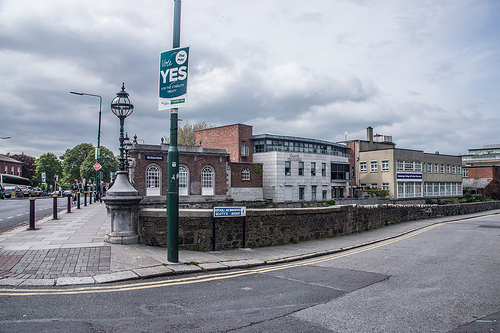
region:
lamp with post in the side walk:
[63, 87, 103, 202]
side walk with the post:
[40, 238, 292, 263]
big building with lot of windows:
[353, 140, 470, 197]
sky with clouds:
[268, 60, 456, 118]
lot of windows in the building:
[396, 161, 459, 190]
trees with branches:
[46, 145, 106, 176]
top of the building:
[259, 129, 336, 150]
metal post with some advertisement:
[153, 53, 195, 267]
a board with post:
[208, 206, 252, 254]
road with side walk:
[7, 187, 109, 279]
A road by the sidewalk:
[1, 210, 498, 330]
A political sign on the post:
[158, 50, 187, 107]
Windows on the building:
[147, 163, 217, 191]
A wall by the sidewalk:
[142, 200, 499, 237]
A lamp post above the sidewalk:
[110, 85, 135, 168]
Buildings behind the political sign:
[128, 125, 466, 199]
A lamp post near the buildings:
[70, 89, 102, 201]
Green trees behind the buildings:
[35, 148, 112, 190]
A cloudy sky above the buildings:
[2, 3, 499, 153]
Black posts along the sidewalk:
[24, 190, 98, 227]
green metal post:
[166, 1, 188, 263]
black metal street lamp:
[107, 80, 135, 175]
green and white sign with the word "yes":
[155, 44, 197, 118]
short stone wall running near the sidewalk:
[125, 188, 498, 246]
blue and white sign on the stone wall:
[208, 200, 248, 223]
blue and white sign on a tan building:
[391, 169, 429, 185]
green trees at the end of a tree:
[26, 144, 118, 196]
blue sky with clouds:
[0, 2, 499, 167]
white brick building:
[250, 148, 355, 204]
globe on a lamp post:
[109, 93, 133, 121]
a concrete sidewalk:
[1, 177, 116, 287]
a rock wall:
[146, 193, 449, 253]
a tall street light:
[69, 71, 108, 185]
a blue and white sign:
[191, 201, 254, 235]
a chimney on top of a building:
[359, 117, 376, 154]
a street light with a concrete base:
[97, 74, 139, 265]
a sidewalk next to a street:
[181, 209, 479, 301]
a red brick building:
[155, 147, 251, 195]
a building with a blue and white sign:
[357, 154, 472, 207]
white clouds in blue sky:
[12, 23, 42, 60]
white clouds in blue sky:
[212, 26, 242, 44]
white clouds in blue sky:
[278, 26, 305, 61]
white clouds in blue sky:
[320, 29, 375, 110]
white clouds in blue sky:
[367, 23, 457, 68]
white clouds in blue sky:
[367, 72, 424, 113]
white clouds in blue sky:
[211, 63, 268, 110]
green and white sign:
[140, 51, 192, 98]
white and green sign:
[150, 41, 198, 116]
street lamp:
[102, 82, 147, 130]